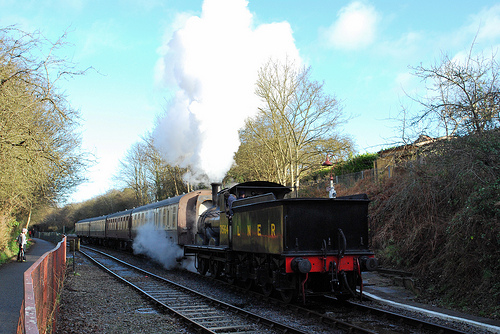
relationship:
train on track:
[76, 152, 375, 299] [63, 225, 497, 332]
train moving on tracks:
[76, 152, 375, 299] [68, 236, 497, 332]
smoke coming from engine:
[127, 11, 281, 288] [187, 165, 374, 306]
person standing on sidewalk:
[12, 225, 33, 265] [0, 231, 61, 330]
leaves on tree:
[0, 23, 87, 230] [1, 25, 101, 257]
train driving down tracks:
[76, 152, 375, 299] [68, 236, 497, 332]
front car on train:
[190, 171, 367, 297] [61, 173, 386, 301]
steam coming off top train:
[170, 16, 291, 195] [35, 122, 447, 312]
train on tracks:
[76, 152, 375, 299] [68, 236, 497, 332]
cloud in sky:
[322, 0, 379, 62] [2, 0, 498, 208]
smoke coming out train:
[125, 213, 195, 275] [75, 179, 372, 311]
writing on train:
[215, 219, 280, 239] [187, 165, 367, 297]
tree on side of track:
[1, 25, 101, 257] [79, 248, 497, 332]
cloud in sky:
[322, 0, 379, 62] [1, 37, 453, 178]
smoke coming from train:
[127, 11, 309, 188] [85, 119, 443, 331]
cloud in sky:
[322, 0, 379, 62] [294, 28, 395, 108]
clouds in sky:
[348, 26, 445, 83] [1, 6, 495, 191]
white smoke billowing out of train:
[167, 102, 272, 199] [61, 173, 386, 301]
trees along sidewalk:
[0, 21, 107, 251] [0, 236, 54, 332]